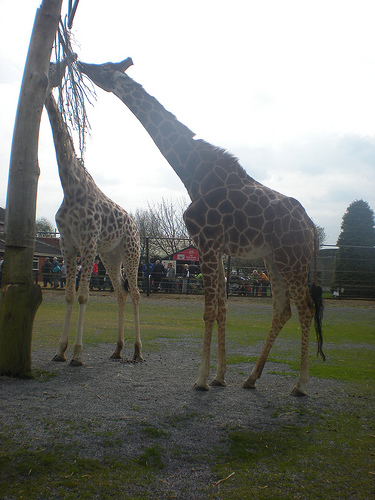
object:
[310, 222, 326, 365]
tail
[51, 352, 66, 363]
hoof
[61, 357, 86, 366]
hoof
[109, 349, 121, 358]
hoof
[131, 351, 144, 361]
hoof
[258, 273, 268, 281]
shirt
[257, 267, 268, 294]
person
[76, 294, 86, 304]
knee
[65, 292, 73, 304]
knee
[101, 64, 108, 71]
eye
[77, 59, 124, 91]
face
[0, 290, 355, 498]
pen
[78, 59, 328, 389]
giraffe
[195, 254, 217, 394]
legs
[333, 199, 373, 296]
bush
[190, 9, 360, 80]
clouds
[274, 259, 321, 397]
legs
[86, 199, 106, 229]
pattern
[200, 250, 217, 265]
spot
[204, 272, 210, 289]
spot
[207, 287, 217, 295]
spot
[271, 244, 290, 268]
spot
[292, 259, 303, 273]
spot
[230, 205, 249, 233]
spot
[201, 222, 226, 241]
spot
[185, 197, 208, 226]
spot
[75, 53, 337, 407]
giraffe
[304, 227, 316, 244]
spot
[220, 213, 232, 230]
spot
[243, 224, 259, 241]
spot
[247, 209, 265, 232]
spot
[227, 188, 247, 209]
spot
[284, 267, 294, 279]
spot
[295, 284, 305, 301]
spot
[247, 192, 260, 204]
spot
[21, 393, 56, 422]
gravel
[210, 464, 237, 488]
twig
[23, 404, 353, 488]
ground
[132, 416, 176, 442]
grass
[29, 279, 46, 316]
knothole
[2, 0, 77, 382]
tree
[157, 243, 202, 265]
facade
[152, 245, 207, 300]
building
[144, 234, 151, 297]
pole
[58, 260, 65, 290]
woman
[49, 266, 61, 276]
shirt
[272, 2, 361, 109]
sky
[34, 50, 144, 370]
giraffe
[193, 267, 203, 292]
person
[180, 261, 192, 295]
person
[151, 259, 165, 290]
person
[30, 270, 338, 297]
fence